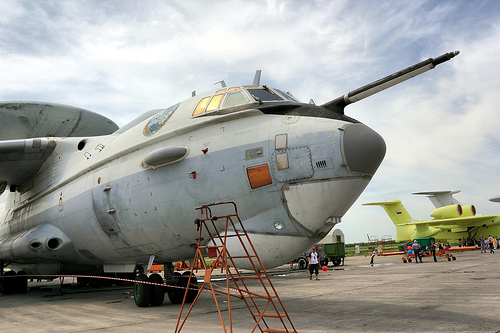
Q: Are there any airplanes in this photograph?
A: Yes, there is an airplane.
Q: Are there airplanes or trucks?
A: Yes, there is an airplane.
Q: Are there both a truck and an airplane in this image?
A: No, there is an airplane but no trucks.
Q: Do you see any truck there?
A: No, there are no trucks.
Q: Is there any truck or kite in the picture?
A: No, there are no trucks or kites.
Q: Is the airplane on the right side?
A: Yes, the airplane is on the right of the image.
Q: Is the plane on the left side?
A: No, the plane is on the right of the image.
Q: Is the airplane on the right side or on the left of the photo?
A: The airplane is on the right of the image.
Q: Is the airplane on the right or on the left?
A: The airplane is on the right of the image.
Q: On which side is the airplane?
A: The airplane is on the right of the image.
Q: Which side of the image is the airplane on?
A: The airplane is on the right of the image.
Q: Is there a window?
A: Yes, there is a window.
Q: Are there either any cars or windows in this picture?
A: Yes, there is a window.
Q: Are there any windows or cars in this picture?
A: Yes, there is a window.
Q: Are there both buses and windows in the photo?
A: No, there is a window but no buses.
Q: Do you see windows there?
A: Yes, there is a window.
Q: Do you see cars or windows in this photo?
A: Yes, there is a window.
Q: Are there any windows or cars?
A: Yes, there is a window.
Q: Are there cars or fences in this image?
A: No, there are no cars or fences.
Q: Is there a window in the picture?
A: Yes, there is a window.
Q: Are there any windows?
A: Yes, there is a window.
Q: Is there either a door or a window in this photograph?
A: Yes, there is a window.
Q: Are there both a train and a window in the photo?
A: No, there is a window but no trains.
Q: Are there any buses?
A: No, there are no buses.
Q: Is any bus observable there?
A: No, there are no buses.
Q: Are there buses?
A: No, there are no buses.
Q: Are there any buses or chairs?
A: No, there are no buses or chairs.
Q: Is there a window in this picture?
A: Yes, there is a window.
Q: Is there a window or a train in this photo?
A: Yes, there is a window.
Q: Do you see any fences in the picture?
A: No, there are no fences.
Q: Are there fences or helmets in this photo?
A: No, there are no fences or helmets.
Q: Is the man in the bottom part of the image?
A: Yes, the man is in the bottom of the image.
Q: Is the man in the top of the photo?
A: No, the man is in the bottom of the image.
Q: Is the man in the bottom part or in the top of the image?
A: The man is in the bottom of the image.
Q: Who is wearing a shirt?
A: The man is wearing a shirt.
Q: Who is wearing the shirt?
A: The man is wearing a shirt.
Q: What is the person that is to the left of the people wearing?
A: The man is wearing a shirt.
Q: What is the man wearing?
A: The man is wearing a shirt.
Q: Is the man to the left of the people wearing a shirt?
A: Yes, the man is wearing a shirt.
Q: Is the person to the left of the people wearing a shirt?
A: Yes, the man is wearing a shirt.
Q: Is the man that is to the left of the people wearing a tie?
A: No, the man is wearing a shirt.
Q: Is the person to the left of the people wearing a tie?
A: No, the man is wearing a shirt.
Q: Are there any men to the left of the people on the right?
A: Yes, there is a man to the left of the people.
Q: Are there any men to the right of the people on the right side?
A: No, the man is to the left of the people.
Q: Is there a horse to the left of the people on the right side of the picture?
A: No, there is a man to the left of the people.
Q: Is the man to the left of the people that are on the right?
A: Yes, the man is to the left of the people.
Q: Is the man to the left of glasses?
A: No, the man is to the left of the people.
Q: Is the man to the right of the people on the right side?
A: No, the man is to the left of the people.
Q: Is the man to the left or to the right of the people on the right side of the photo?
A: The man is to the left of the people.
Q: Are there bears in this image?
A: No, there are no bears.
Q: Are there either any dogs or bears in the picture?
A: No, there are no bears or dogs.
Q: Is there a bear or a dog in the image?
A: No, there are no bears or dogs.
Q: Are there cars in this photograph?
A: No, there are no cars.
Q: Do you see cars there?
A: No, there are no cars.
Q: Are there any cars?
A: No, there are no cars.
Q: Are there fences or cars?
A: No, there are no cars or fences.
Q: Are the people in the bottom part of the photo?
A: Yes, the people are in the bottom of the image.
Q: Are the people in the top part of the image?
A: No, the people are in the bottom of the image.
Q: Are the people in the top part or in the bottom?
A: The people are in the bottom of the image.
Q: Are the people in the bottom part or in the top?
A: The people are in the bottom of the image.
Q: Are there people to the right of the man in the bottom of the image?
A: Yes, there are people to the right of the man.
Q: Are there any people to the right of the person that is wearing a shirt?
A: Yes, there are people to the right of the man.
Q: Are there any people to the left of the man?
A: No, the people are to the right of the man.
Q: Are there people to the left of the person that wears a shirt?
A: No, the people are to the right of the man.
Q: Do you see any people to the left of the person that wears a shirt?
A: No, the people are to the right of the man.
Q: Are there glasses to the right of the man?
A: No, there are people to the right of the man.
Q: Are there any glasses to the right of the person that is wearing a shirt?
A: No, there are people to the right of the man.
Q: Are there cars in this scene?
A: No, there are no cars.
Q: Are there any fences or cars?
A: No, there are no cars or fences.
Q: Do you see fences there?
A: No, there are no fences.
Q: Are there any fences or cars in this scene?
A: No, there are no fences or cars.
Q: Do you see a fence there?
A: No, there are no fences.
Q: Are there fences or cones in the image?
A: No, there are no fences or cones.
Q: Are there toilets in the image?
A: No, there are no toilets.